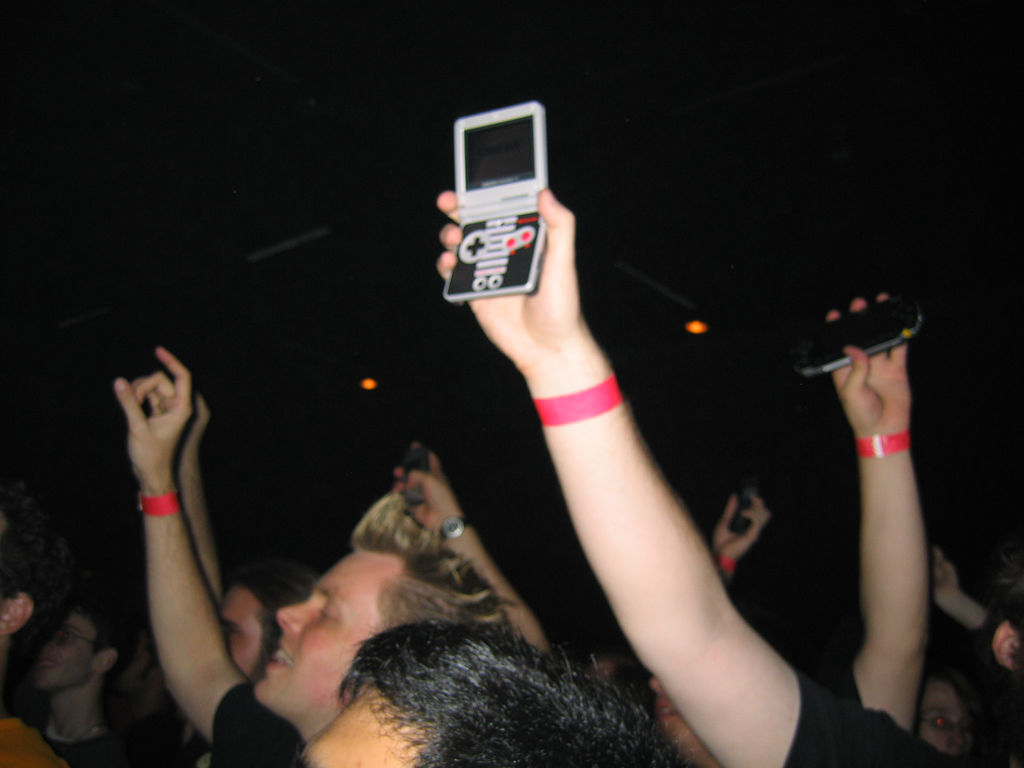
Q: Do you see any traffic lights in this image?
A: No, there are no traffic lights.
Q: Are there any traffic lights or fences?
A: No, there are no traffic lights or fences.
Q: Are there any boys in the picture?
A: No, there are no boys.